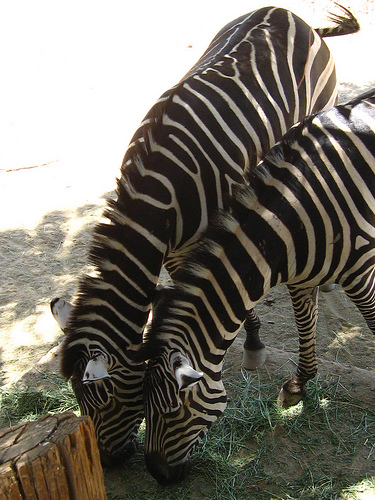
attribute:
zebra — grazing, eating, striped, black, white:
[51, 3, 365, 469]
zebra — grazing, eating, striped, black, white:
[140, 80, 374, 484]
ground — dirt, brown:
[1, 164, 370, 499]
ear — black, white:
[82, 354, 113, 385]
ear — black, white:
[49, 295, 76, 332]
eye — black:
[163, 405, 182, 419]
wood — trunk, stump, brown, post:
[2, 410, 105, 498]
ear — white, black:
[175, 365, 209, 389]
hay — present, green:
[2, 370, 374, 496]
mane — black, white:
[65, 178, 125, 375]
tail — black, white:
[311, 1, 364, 40]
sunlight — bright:
[1, 296, 63, 393]